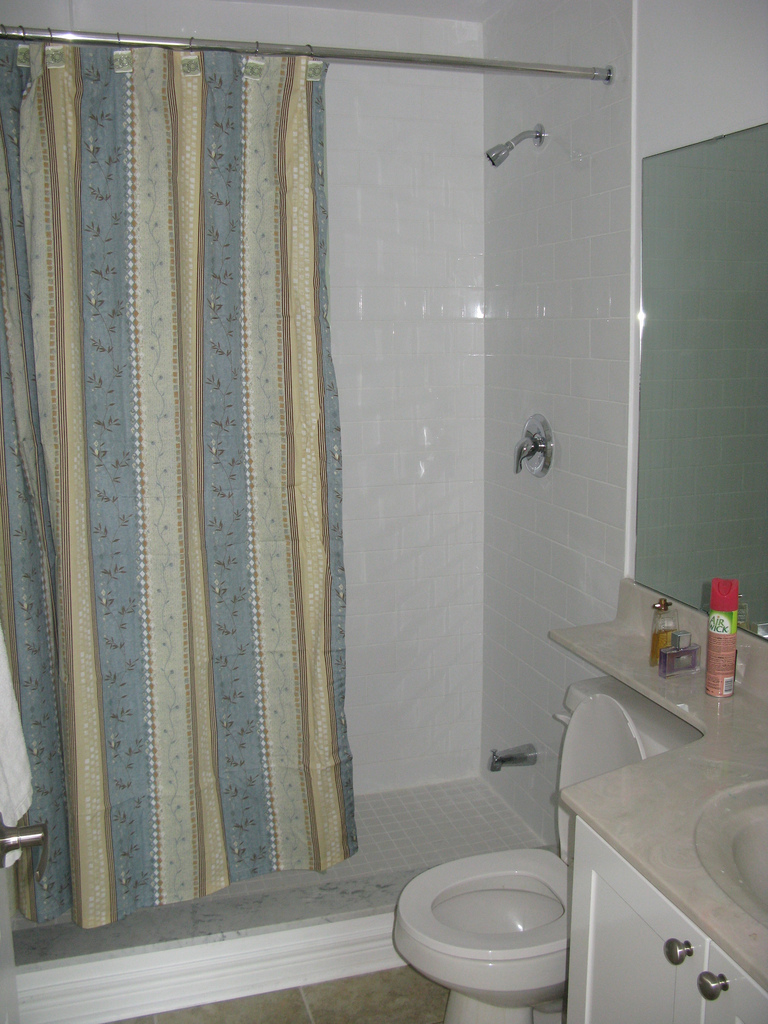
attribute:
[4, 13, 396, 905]
curtain — hanging from rod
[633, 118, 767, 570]
mirror — large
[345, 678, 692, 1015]
toilet — white, porcelain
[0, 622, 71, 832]
towel — white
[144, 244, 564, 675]
shower — off white, tiled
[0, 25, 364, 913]
shower curtain — striped, in the bathroom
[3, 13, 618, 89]
curtain rod — chrome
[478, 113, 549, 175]
showerhead — chrome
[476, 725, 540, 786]
faucet — chrome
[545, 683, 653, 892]
toilet lid — upright position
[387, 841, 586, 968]
toilet seat — down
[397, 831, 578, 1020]
toilet bowl — white, porcelain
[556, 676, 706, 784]
tank lid — in place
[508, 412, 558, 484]
water control — silver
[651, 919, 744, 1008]
knobs — silver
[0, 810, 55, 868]
handle — silver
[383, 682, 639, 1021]
toilet — white, porcelain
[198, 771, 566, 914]
shower floor — tiled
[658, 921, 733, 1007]
knob — silver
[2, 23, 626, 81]
rod — silver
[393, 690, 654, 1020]
toilet — white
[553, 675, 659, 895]
lid — open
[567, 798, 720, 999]
cabinets — white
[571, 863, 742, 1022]
handles — silver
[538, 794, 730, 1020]
cabinets — white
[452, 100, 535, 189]
shower head — silver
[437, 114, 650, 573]
wall — white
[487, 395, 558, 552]
faucet — silver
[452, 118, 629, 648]
wall — white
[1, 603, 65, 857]
towel — white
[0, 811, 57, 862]
handle — silver door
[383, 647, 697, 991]
toliet — white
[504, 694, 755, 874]
sink — white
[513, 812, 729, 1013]
cabinet — white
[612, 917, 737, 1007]
knobs — silver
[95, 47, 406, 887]
curtain — stripes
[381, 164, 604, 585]
wall — tiled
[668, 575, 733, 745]
bottle — red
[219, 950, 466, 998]
floor — beige